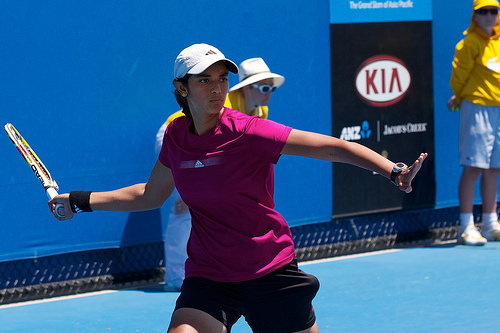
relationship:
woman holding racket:
[46, 42, 428, 332] [4, 121, 65, 215]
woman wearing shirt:
[46, 42, 428, 332] [154, 105, 295, 282]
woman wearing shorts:
[46, 42, 428, 332] [170, 253, 319, 332]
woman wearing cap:
[46, 42, 428, 332] [170, 42, 240, 81]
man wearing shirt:
[155, 54, 286, 290] [166, 91, 269, 126]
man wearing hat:
[155, 54, 286, 290] [229, 56, 285, 92]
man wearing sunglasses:
[155, 54, 286, 290] [251, 81, 276, 95]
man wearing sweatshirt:
[446, 1, 499, 247] [449, 12, 499, 106]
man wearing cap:
[446, 1, 499, 247] [470, 0, 499, 11]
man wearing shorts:
[446, 1, 499, 247] [458, 96, 499, 172]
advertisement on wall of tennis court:
[326, 0, 435, 223] [1, 1, 499, 332]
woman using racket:
[46, 42, 428, 332] [4, 121, 65, 215]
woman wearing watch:
[46, 42, 428, 332] [388, 160, 406, 185]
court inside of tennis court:
[1, 234, 499, 333] [1, 1, 499, 332]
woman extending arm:
[46, 42, 428, 332] [251, 117, 400, 182]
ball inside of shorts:
[297, 270, 321, 300] [170, 253, 319, 332]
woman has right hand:
[46, 42, 428, 332] [47, 191, 74, 222]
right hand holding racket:
[47, 191, 74, 222] [4, 121, 65, 215]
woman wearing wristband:
[46, 42, 428, 332] [68, 188, 94, 214]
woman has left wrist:
[46, 42, 428, 332] [388, 161, 399, 186]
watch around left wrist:
[388, 160, 406, 185] [388, 161, 399, 186]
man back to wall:
[155, 54, 286, 290] [1, 1, 499, 257]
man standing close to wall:
[155, 54, 286, 290] [1, 1, 499, 257]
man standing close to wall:
[446, 1, 499, 247] [1, 1, 499, 257]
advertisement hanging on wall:
[326, 0, 435, 223] [1, 1, 499, 257]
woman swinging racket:
[46, 42, 428, 332] [4, 121, 65, 215]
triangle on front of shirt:
[193, 159, 205, 168] [154, 105, 295, 282]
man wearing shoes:
[446, 1, 499, 247] [453, 219, 498, 244]